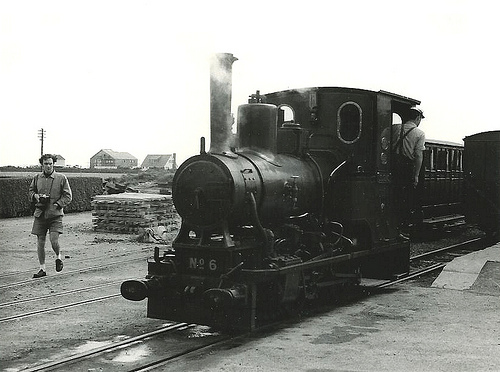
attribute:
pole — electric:
[30, 125, 55, 167]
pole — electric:
[11, 110, 83, 162]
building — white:
[88, 145, 145, 178]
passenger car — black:
[407, 123, 474, 250]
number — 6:
[189, 253, 225, 276]